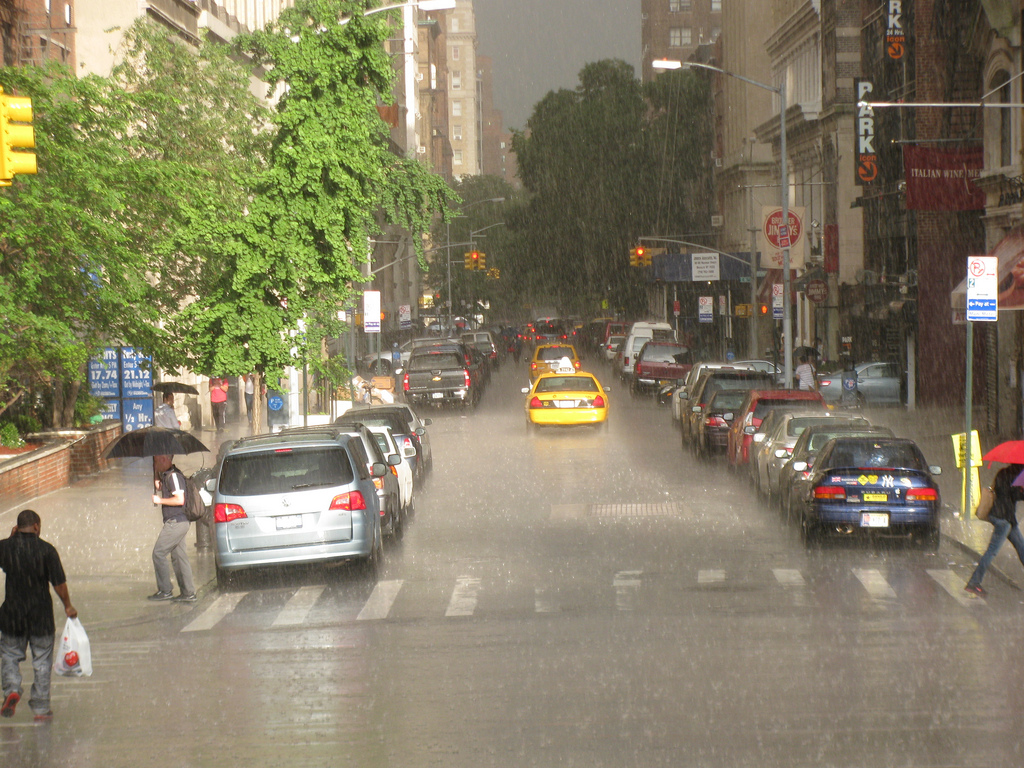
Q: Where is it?
A: This is at the street.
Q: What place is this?
A: It is a street.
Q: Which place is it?
A: It is a street.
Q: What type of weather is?
A: It is cloudy.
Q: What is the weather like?
A: It is cloudy.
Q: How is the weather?
A: It is cloudy.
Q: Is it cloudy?
A: Yes, it is cloudy.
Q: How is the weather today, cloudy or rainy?
A: It is cloudy.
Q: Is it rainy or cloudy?
A: It is cloudy.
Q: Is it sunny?
A: No, it is cloudy.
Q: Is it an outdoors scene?
A: Yes, it is outdoors.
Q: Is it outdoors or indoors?
A: It is outdoors.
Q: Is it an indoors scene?
A: No, it is outdoors.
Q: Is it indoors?
A: No, it is outdoors.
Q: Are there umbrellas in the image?
A: Yes, there is an umbrella.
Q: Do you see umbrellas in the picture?
A: Yes, there is an umbrella.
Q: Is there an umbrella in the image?
A: Yes, there is an umbrella.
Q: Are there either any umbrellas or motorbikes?
A: Yes, there is an umbrella.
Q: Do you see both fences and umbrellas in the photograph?
A: No, there is an umbrella but no fences.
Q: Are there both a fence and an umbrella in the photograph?
A: No, there is an umbrella but no fences.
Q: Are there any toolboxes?
A: No, there are no toolboxes.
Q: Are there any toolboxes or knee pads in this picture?
A: No, there are no toolboxes or knee pads.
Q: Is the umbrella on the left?
A: Yes, the umbrella is on the left of the image.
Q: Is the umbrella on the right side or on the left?
A: The umbrella is on the left of the image.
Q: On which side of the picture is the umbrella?
A: The umbrella is on the left of the image.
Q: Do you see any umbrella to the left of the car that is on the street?
A: Yes, there is an umbrella to the left of the car.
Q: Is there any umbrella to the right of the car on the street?
A: No, the umbrella is to the left of the car.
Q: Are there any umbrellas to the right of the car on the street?
A: No, the umbrella is to the left of the car.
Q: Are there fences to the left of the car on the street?
A: No, there is an umbrella to the left of the car.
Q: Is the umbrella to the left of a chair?
A: No, the umbrella is to the left of the car.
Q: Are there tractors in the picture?
A: No, there are no tractors.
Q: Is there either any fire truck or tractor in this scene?
A: No, there are no tractors or fire trucks.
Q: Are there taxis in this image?
A: Yes, there is a taxi.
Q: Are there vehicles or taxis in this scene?
A: Yes, there is a taxi.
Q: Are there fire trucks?
A: No, there are no fire trucks.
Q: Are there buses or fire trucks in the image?
A: No, there are no fire trucks or buses.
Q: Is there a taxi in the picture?
A: Yes, there is a taxi.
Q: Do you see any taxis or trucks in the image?
A: Yes, there is a taxi.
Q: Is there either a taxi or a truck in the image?
A: Yes, there is a taxi.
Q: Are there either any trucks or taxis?
A: Yes, there is a taxi.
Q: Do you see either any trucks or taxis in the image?
A: Yes, there is a taxi.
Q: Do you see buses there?
A: No, there are no buses.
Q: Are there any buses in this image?
A: No, there are no buses.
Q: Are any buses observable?
A: No, there are no buses.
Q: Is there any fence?
A: No, there are no fences.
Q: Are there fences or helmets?
A: No, there are no fences or helmets.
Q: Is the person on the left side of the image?
A: Yes, the person is on the left of the image.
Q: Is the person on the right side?
A: No, the person is on the left of the image.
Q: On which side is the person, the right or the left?
A: The person is on the left of the image.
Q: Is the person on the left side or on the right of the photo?
A: The person is on the left of the image.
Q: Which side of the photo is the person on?
A: The person is on the left of the image.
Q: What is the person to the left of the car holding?
A: The person is holding the umbrella.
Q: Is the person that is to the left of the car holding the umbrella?
A: Yes, the person is holding the umbrella.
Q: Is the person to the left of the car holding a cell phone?
A: No, the person is holding the umbrella.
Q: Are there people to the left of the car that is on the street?
A: Yes, there is a person to the left of the car.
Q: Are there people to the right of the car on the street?
A: No, the person is to the left of the car.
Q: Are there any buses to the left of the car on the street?
A: No, there is a person to the left of the car.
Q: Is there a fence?
A: No, there are no fences.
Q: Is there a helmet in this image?
A: No, there are no helmets.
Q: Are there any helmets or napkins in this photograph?
A: No, there are no helmets or napkins.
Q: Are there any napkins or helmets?
A: No, there are no helmets or napkins.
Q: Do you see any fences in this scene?
A: No, there are no fences.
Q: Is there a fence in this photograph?
A: No, there are no fences.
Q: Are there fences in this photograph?
A: No, there are no fences.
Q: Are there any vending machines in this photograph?
A: No, there are no vending machines.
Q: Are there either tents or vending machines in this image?
A: No, there are no vending machines or tents.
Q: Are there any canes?
A: No, there are no canes.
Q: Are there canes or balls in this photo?
A: No, there are no canes or balls.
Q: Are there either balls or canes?
A: No, there are no canes or balls.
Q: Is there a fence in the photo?
A: No, there are no fences.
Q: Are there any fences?
A: No, there are no fences.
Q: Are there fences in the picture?
A: No, there are no fences.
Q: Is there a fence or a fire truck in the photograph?
A: No, there are no fences or fire trucks.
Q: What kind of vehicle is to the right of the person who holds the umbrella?
A: The vehicle is a car.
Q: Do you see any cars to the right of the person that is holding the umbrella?
A: Yes, there is a car to the right of the person.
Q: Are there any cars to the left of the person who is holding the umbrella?
A: No, the car is to the right of the person.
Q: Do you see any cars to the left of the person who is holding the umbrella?
A: No, the car is to the right of the person.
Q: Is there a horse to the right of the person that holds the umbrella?
A: No, there is a car to the right of the person.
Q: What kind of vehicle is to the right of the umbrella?
A: The vehicle is a car.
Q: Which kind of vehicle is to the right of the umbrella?
A: The vehicle is a car.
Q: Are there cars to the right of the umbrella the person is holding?
A: Yes, there is a car to the right of the umbrella.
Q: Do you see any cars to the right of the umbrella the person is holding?
A: Yes, there is a car to the right of the umbrella.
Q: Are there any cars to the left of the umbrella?
A: No, the car is to the right of the umbrella.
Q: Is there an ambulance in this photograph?
A: No, there are no ambulances.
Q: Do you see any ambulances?
A: No, there are no ambulances.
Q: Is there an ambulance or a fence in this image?
A: No, there are no ambulances or fences.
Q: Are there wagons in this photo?
A: No, there are no wagons.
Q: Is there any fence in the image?
A: No, there are no fences.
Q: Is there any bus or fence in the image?
A: No, there are no fences or buses.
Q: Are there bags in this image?
A: Yes, there is a bag.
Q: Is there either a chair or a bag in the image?
A: Yes, there is a bag.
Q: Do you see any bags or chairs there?
A: Yes, there is a bag.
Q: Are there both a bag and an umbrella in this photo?
A: Yes, there are both a bag and an umbrella.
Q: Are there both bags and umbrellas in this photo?
A: Yes, there are both a bag and an umbrella.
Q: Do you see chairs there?
A: No, there are no chairs.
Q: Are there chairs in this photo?
A: No, there are no chairs.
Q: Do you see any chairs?
A: No, there are no chairs.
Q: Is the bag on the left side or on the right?
A: The bag is on the left of the image.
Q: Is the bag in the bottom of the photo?
A: Yes, the bag is in the bottom of the image.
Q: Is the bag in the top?
A: No, the bag is in the bottom of the image.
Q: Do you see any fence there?
A: No, there are no fences.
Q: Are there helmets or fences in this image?
A: No, there are no fences or helmets.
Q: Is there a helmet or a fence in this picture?
A: No, there are no fences or helmets.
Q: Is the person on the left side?
A: Yes, the person is on the left of the image.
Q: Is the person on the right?
A: No, the person is on the left of the image.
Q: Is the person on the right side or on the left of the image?
A: The person is on the left of the image.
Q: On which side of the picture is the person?
A: The person is on the left of the image.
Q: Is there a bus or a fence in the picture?
A: No, there are no fences or buses.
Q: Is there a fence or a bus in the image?
A: No, there are no fences or buses.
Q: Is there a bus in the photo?
A: No, there are no buses.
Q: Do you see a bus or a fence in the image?
A: No, there are no buses or fences.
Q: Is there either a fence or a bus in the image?
A: No, there are no buses or fences.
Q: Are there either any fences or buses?
A: No, there are no buses or fences.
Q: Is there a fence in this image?
A: No, there are no fences.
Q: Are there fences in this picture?
A: No, there are no fences.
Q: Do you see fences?
A: No, there are no fences.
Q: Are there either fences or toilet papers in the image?
A: No, there are no fences or toilet papers.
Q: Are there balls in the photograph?
A: No, there are no balls.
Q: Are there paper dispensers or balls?
A: No, there are no balls or paper dispensers.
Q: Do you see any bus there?
A: No, there are no buses.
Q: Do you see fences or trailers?
A: No, there are no fences or trailers.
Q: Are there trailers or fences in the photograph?
A: No, there are no fences or trailers.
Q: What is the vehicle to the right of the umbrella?
A: The vehicle is a car.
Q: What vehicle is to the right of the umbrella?
A: The vehicle is a car.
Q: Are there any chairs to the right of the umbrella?
A: No, there is a car to the right of the umbrella.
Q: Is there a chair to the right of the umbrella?
A: No, there is a car to the right of the umbrella.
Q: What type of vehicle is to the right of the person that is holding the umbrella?
A: The vehicle is a car.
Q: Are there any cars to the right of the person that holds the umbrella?
A: Yes, there is a car to the right of the person.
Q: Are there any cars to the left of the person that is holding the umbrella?
A: No, the car is to the right of the person.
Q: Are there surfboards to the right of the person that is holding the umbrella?
A: No, there is a car to the right of the person.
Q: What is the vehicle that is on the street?
A: The vehicle is a car.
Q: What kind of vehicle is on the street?
A: The vehicle is a car.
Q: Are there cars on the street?
A: Yes, there is a car on the street.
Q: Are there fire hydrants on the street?
A: No, there is a car on the street.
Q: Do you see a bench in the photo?
A: No, there are no benches.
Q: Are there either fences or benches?
A: No, there are no benches or fences.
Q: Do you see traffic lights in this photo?
A: Yes, there is a traffic light.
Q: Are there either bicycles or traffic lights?
A: Yes, there is a traffic light.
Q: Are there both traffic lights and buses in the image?
A: No, there is a traffic light but no buses.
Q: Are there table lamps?
A: No, there are no table lamps.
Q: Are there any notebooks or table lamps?
A: No, there are no table lamps or notebooks.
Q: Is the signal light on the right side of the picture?
A: No, the signal light is on the left of the image.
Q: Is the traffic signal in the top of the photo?
A: Yes, the traffic signal is in the top of the image.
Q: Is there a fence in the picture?
A: No, there are no fences.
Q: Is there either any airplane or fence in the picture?
A: No, there are no fences or airplanes.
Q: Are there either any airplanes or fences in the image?
A: No, there are no fences or airplanes.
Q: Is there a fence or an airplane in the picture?
A: No, there are no fences or airplanes.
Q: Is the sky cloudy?
A: Yes, the sky is cloudy.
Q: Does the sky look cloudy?
A: Yes, the sky is cloudy.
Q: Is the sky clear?
A: No, the sky is cloudy.